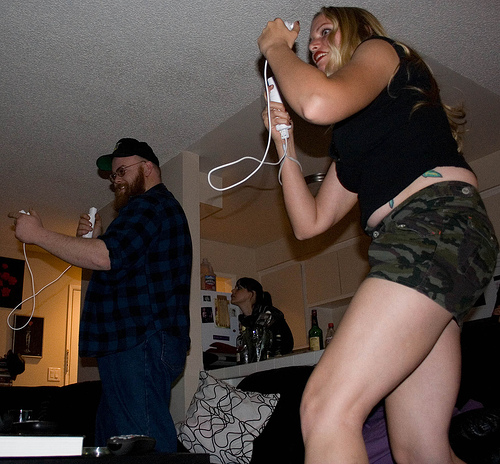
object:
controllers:
[250, 12, 301, 148]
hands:
[252, 12, 305, 61]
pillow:
[170, 364, 283, 464]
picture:
[9, 312, 48, 364]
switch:
[45, 364, 64, 384]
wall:
[0, 205, 107, 444]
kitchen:
[239, 221, 399, 373]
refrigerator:
[211, 297, 232, 331]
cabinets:
[298, 246, 346, 307]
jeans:
[89, 342, 194, 464]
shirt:
[318, 40, 472, 221]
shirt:
[76, 181, 198, 370]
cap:
[93, 133, 164, 178]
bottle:
[304, 304, 327, 356]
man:
[0, 128, 210, 464]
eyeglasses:
[109, 158, 148, 183]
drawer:
[257, 258, 312, 352]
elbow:
[289, 190, 329, 244]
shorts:
[352, 181, 500, 336]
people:
[223, 268, 297, 377]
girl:
[230, 0, 500, 464]